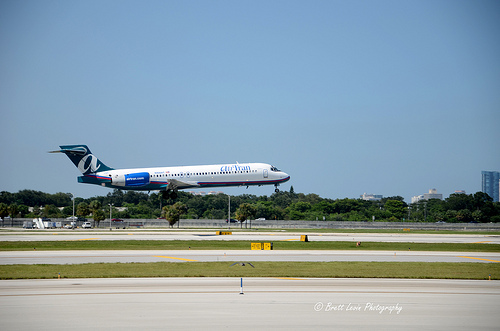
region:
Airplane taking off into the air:
[37, 118, 317, 208]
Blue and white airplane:
[49, 132, 311, 212]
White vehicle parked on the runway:
[75, 214, 95, 236]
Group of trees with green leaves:
[154, 192, 191, 236]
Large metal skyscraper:
[473, 161, 498, 200]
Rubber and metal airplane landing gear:
[266, 176, 288, 200]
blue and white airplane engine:
[107, 168, 159, 193]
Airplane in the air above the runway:
[34, 126, 304, 217]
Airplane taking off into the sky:
[41, 118, 346, 227]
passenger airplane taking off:
[43, 134, 309, 216]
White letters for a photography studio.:
[285, 293, 433, 328]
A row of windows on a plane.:
[148, 167, 263, 200]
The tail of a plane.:
[29, 98, 113, 242]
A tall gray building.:
[462, 149, 499, 227]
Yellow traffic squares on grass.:
[233, 237, 294, 267]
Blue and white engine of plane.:
[93, 166, 165, 214]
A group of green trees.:
[262, 182, 483, 250]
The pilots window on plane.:
[258, 156, 297, 210]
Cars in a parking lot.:
[2, 213, 105, 250]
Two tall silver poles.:
[97, 188, 242, 240]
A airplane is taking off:
[44, 123, 316, 230]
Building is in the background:
[463, 160, 498, 198]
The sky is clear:
[7, 11, 498, 198]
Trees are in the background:
[2, 177, 498, 221]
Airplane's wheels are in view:
[137, 176, 299, 209]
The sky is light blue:
[11, 4, 490, 169]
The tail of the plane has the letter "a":
[52, 130, 118, 180]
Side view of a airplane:
[36, 115, 341, 225]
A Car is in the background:
[75, 215, 95, 235]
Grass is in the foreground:
[3, 263, 493, 275]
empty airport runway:
[8, 276, 497, 321]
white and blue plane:
[48, 141, 293, 207]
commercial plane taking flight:
[45, 137, 293, 203]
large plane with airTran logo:
[44, 137, 304, 204]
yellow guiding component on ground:
[248, 240, 275, 253]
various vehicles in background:
[18, 213, 98, 229]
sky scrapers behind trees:
[357, 166, 498, 221]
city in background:
[356, 167, 494, 222]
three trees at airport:
[157, 196, 189, 231]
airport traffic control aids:
[214, 225, 366, 253]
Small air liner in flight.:
[56, 127, 350, 213]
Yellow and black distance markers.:
[200, 215, 329, 254]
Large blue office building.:
[471, 165, 498, 210]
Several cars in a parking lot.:
[20, 212, 101, 237]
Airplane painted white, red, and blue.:
[48, 135, 305, 201]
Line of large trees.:
[3, 188, 498, 227]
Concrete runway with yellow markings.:
[3, 242, 498, 270]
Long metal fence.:
[3, 217, 498, 230]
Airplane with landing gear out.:
[58, 136, 300, 210]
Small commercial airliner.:
[41, 140, 311, 203]